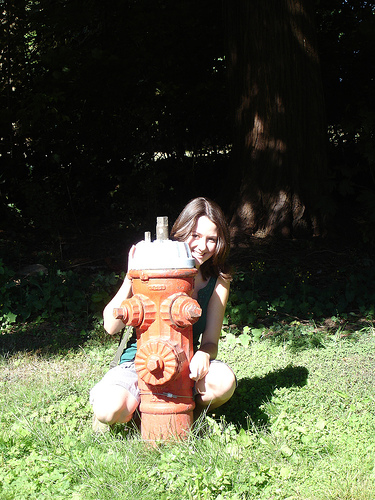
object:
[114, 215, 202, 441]
hydrant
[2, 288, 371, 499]
grass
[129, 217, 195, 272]
cap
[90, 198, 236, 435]
girl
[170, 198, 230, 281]
hair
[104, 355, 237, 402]
shorts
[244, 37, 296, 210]
woods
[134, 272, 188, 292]
red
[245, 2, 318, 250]
tree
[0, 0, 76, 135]
leaves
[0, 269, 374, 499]
ground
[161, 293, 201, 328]
spout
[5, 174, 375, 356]
shade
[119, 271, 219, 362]
shirt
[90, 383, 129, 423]
knee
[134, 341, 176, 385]
valve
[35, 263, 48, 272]
rock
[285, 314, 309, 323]
stick